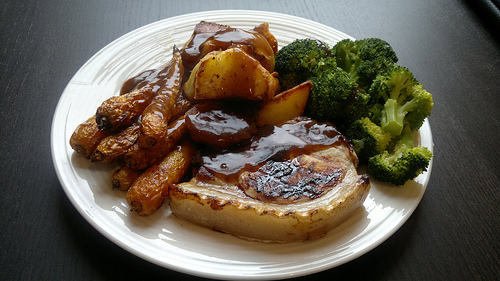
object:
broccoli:
[367, 124, 433, 186]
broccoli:
[367, 64, 434, 136]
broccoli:
[274, 37, 434, 187]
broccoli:
[304, 67, 370, 125]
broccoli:
[274, 38, 332, 90]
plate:
[49, 9, 434, 280]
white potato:
[253, 80, 314, 127]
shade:
[57, 184, 424, 281]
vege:
[367, 124, 434, 187]